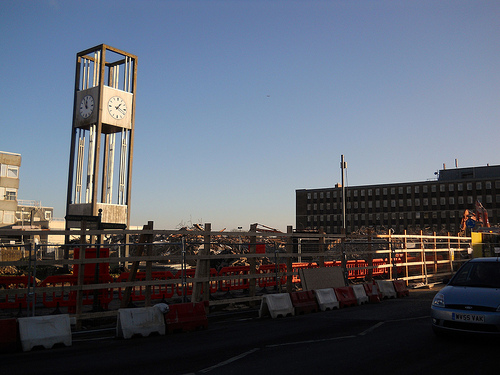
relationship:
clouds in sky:
[258, 128, 344, 185] [29, 10, 453, 185]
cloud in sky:
[41, 192, 296, 232] [0, 3, 476, 221]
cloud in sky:
[27, 188, 296, 232] [2, 1, 479, 265]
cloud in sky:
[27, 188, 296, 232] [0, 3, 476, 221]